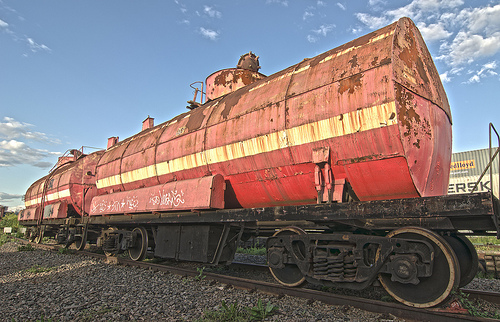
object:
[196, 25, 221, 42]
cloud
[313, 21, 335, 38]
cloud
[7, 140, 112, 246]
car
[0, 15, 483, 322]
train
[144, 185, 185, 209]
graffitti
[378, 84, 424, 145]
rust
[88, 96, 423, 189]
stripes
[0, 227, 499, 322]
train tracks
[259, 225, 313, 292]
car wheel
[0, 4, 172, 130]
blue sky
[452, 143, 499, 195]
behind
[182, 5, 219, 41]
cloud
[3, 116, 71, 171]
cloud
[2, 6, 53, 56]
cloud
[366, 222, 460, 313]
wheels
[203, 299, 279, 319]
grass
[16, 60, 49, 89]
clouds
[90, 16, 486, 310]
car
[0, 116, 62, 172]
clouds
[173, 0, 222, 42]
clouds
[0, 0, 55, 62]
clouds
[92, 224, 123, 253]
wheel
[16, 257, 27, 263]
gravel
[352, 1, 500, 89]
cloud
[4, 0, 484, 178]
sky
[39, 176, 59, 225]
ladder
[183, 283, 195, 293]
gravel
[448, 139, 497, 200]
building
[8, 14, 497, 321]
carts